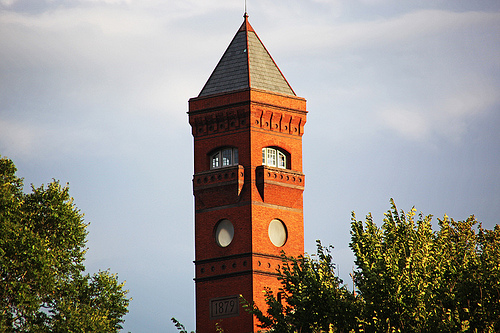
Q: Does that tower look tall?
A: Yes, the tower is tall.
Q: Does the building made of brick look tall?
A: Yes, the tower is tall.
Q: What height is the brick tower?
A: The tower is tall.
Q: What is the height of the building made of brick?
A: The tower is tall.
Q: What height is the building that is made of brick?
A: The tower is tall.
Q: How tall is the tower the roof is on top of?
A: The tower is tall.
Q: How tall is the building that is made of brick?
A: The tower is tall.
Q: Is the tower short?
A: No, the tower is tall.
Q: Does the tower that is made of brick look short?
A: No, the tower is tall.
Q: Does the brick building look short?
A: No, the tower is tall.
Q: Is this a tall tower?
A: Yes, this is a tall tower.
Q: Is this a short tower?
A: No, this is a tall tower.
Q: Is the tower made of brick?
A: Yes, the tower is made of brick.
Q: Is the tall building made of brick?
A: Yes, the tower is made of brick.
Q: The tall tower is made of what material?
A: The tower is made of brick.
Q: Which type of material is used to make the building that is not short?
A: The tower is made of brick.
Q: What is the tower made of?
A: The tower is made of brick.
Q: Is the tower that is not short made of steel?
A: No, the tower is made of brick.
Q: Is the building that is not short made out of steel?
A: No, the tower is made of brick.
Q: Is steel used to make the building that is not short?
A: No, the tower is made of brick.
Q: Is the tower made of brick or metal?
A: The tower is made of brick.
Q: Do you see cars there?
A: No, there are no cars.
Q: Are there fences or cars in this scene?
A: No, there are no cars or fences.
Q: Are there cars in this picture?
A: No, there are no cars.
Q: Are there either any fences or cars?
A: No, there are no cars or fences.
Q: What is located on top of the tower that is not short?
A: The roof is on top of the tower.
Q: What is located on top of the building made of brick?
A: The roof is on top of the tower.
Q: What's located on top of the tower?
A: The roof is on top of the tower.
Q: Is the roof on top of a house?
A: No, the roof is on top of the tower.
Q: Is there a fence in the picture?
A: No, there are no fences.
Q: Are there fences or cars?
A: No, there are no fences or cars.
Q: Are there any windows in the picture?
A: Yes, there is a window.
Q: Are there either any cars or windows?
A: Yes, there is a window.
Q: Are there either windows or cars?
A: Yes, there is a window.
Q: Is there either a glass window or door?
A: Yes, there is a glass window.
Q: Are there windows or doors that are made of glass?
A: Yes, the window is made of glass.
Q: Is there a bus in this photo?
A: No, there are no buses.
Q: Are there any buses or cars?
A: No, there are no buses or cars.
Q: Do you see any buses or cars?
A: No, there are no buses or cars.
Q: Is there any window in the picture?
A: Yes, there is a window.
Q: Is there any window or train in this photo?
A: Yes, there is a window.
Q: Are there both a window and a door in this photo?
A: No, there is a window but no doors.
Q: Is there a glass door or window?
A: Yes, there is a glass window.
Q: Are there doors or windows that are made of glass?
A: Yes, the window is made of glass.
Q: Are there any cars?
A: No, there are no cars.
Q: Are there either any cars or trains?
A: No, there are no cars or trains.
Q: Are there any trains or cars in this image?
A: No, there are no cars or trains.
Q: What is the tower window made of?
A: The window is made of glass.